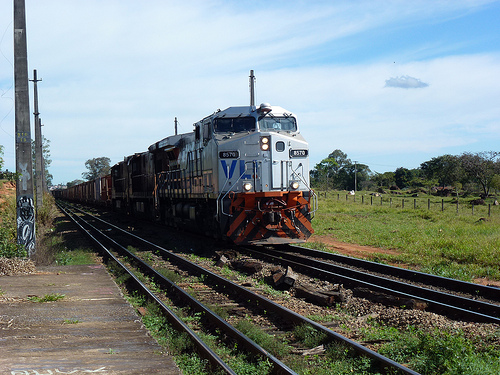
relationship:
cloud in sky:
[288, 5, 480, 145] [1, 5, 483, 139]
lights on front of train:
[235, 172, 257, 195] [102, 124, 308, 241]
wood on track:
[213, 250, 351, 315] [54, 199, 500, 375]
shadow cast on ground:
[47, 200, 157, 255] [46, 169, 498, 374]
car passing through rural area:
[51, 69, 318, 245] [4, 1, 485, 361]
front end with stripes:
[210, 68, 312, 240] [221, 189, 312, 241]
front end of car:
[210, 68, 312, 240] [51, 69, 318, 245]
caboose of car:
[178, 103, 318, 248] [51, 69, 318, 245]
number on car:
[291, 148, 307, 159] [51, 69, 318, 245]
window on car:
[218, 109, 298, 136] [51, 69, 318, 245]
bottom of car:
[98, 202, 211, 229] [51, 69, 318, 245]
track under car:
[248, 245, 498, 327] [51, 69, 318, 245]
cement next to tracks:
[39, 295, 102, 322] [114, 249, 447, 300]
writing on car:
[218, 156, 255, 181] [51, 69, 318, 245]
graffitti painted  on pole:
[16, 168, 36, 257] [11, 0, 36, 253]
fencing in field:
[316, 182, 496, 235] [310, 181, 485, 247]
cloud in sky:
[348, 97, 482, 144] [204, 90, 273, 150]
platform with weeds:
[2, 268, 173, 374] [26, 284, 68, 308]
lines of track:
[133, 254, 344, 372] [76, 228, 309, 358]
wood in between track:
[213, 247, 350, 305] [54, 199, 500, 375]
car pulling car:
[51, 69, 318, 245] [57, 141, 155, 208]